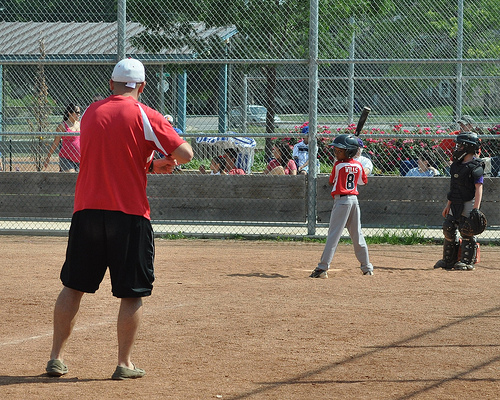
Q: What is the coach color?
A: Red and white.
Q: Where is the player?
A: On field.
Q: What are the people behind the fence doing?
A: Watching the game.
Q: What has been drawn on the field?
A: A baseball diamond.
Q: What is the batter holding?
A: A baseball bat.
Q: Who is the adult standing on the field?
A: The coach.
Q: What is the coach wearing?
A: Black shorts.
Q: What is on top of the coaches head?
A: White cap.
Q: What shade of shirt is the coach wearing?
A: Red with white trim.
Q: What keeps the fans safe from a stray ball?
A: Mesh fence.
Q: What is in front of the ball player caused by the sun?
A: A shadow.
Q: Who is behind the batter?
A: The catcher.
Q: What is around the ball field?
A: A fence.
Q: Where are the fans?
A: In seats.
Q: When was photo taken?
A: Daytime.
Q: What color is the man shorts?
A: Black.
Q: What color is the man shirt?
A: Red.